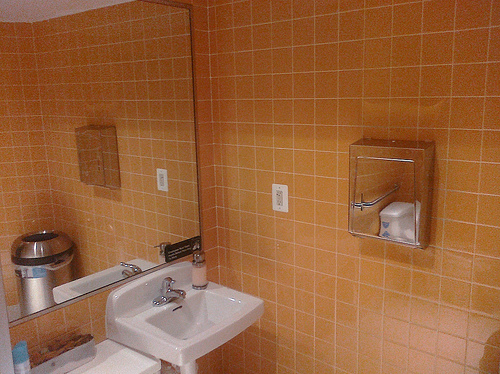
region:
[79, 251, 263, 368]
sink attached to wall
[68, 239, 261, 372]
sink attached to wall is white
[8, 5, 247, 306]
mirror above sink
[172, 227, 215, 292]
canister sitting on sink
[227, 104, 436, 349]
orange tile on wall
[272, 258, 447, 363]
tile has white grout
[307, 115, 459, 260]
metallic container on wall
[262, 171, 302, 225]
white outlet on wall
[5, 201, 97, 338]
trash can in corner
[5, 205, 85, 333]
trash can is metallic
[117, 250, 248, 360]
white sink in bathroom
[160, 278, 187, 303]
silver faucet on sink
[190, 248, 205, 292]
small soap dispenser on counter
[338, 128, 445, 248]
silver paper towel holder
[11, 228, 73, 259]
silver lid to trashcan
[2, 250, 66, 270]
brown rim on trashcan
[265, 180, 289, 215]
white outlet on wall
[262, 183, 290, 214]
white power outlet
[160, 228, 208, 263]
black sign on mirror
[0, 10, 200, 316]
large shiny mirror on wall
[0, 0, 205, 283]
the mirror on the wall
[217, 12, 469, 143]
the wall is tiled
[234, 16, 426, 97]
the tiles are orange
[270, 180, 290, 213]
the outlet on the wall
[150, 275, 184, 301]
the faucet on the sink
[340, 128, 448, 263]
the paper towel dispenser on the wall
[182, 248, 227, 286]
the soap dispenser on the sink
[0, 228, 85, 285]
the waste bin in the corner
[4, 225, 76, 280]
the waste bin is metal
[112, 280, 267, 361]
the sink is white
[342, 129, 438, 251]
A silver paper towel dispenser.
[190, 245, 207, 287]
A container of liquid soap.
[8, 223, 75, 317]
Reflection of a silver trashcan.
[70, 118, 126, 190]
Reflection of a towel dispenser.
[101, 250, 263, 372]
White ceramic sink.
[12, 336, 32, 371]
Can of air freshener.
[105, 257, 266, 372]
A white sink with a silver faucet.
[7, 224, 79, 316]
Large metal trash can.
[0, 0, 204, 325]
Large mirror.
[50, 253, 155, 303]
Reflection of a sink.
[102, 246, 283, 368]
White bathroom sink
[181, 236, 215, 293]
Hand soap on edge of sink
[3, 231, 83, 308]
Garbage can reflecting in mirror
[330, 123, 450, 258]
Paper towel dispenser on wall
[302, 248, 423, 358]
Orange tile on walls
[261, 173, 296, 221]
Electric socket in wall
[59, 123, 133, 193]
Paper towel dispenser reflecting in mirror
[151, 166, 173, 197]
Electric socket reflecting in mirror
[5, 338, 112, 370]
Items on back of toilet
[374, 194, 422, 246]
Toilet reflecting in paper towel dispenser